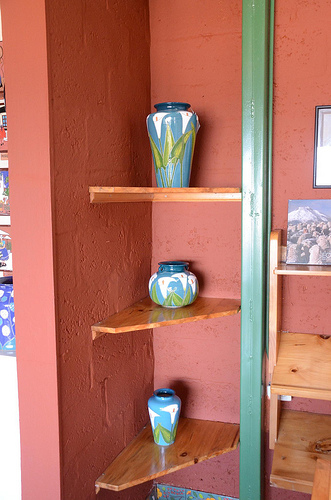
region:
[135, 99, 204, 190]
A vase on the top shelf.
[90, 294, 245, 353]
Wooden shelf in the middle.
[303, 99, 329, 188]
Picture hanging on the wall.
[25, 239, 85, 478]
A pink concrete wall.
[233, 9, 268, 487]
Greene pole on the wall.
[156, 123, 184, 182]
Flowers on a tall vase.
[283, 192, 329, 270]
Picture sitting on a shelf.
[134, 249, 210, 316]
A small, circular vase.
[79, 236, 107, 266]
Holes in the concrete.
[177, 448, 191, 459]
A knot on the shelf.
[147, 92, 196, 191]
Vase on the shelf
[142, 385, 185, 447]
small vase on a shelf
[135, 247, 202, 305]
flower pot on the shelf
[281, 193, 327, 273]
picture on a shelf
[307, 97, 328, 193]
picture in a frame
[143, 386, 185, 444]
blue vase in a shelf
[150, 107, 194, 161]
flowers on a vase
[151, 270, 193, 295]
lilies on a blue vase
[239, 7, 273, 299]
green beam on the shelf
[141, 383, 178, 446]
vase on the bottom shelf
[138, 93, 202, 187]
blue vase on a shelf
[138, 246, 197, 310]
blue vase on a shelf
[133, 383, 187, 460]
blue vase on a shelf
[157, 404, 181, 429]
Lilies on a vase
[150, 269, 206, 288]
flowers on a vase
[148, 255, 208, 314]
blue flower pot on a shelf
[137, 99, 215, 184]
large blue vase on shelf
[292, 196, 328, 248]
picture on the shelf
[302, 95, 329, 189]
picture in the frame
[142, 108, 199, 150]
Lilies on the shelf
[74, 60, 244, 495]
vases on a shelf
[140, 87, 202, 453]
the vases are blue white and green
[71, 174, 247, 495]
the shelves are brown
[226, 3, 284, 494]
green post next to shelves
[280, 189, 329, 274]
picture on the shelf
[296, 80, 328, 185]
picture above the shelf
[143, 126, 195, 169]
leaves on vase are green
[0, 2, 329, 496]
wall made of brick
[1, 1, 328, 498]
the wall is red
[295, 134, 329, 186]
light shining on picture